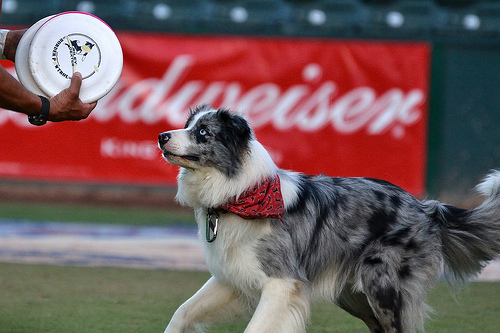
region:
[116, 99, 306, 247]
Dog with a scarf around neck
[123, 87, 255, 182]
Dog has blue eyes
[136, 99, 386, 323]
Dog is black white and gray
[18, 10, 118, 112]
Frisbies in mans hand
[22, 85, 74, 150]
Watch on mans hand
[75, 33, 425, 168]
Budweiser sign in the background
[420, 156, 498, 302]
Dog has a fluffy tail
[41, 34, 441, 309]
Dog waiting to catch some frisbies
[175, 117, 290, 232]
Red bandanna on dog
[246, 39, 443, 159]
Banner is red & white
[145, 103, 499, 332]
Black gray white dog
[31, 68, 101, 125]
Hand holding white round frisbee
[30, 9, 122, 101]
Small white round frisbee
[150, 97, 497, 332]
Dog staring at white frisbee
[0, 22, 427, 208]
Large red Budweiser banner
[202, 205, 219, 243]
Green lock on red handkerchief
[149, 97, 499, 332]
Dog wearing red handkerchief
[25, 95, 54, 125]
Black watch on wrist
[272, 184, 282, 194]
Small black dog on red handkerchief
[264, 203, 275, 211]
Small black dog on red handkerchief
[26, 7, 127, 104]
The frisbee is round.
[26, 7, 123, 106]
The frisbee is black and white.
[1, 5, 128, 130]
Two hands holding two frisbees.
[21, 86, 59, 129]
The watch has a black band.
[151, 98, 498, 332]
The dog is black, white and gray.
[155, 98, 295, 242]
Kerchief around the dog's neck.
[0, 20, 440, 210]
Banner name is partially hidden.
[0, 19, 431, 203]
The banner is red and white.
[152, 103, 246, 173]
The dog has a black nose.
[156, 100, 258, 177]
The dog's eye is open.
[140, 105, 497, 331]
dog looking at frisbee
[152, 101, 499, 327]
white, gray, and black dog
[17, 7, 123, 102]
two white frisbees with black writing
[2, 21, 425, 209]
red budweiser sign with white letters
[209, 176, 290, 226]
red bandana dog is wearing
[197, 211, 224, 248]
silver hook hanging from dog's neck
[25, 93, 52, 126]
watch on arm holding frisbees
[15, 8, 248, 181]
dog's face looking at frisbees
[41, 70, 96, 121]
hand holding frisbees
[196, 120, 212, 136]
blue eye of the dog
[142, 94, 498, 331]
Dog staring at frisbees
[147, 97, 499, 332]
Gray, black and white dog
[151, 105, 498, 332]
Dog wearing green lock on handkerchief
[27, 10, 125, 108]
Round frisbee is white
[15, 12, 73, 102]
Round frisbee is white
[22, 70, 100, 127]
Hand holding white frisbee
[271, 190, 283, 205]
Black dog on red handkerchief